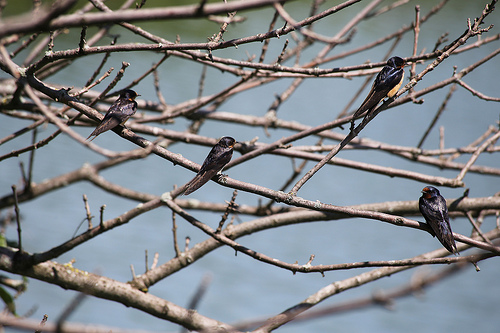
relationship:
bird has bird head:
[417, 184, 456, 251] [418, 180, 443, 197]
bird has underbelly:
[352, 57, 404, 123] [389, 70, 404, 98]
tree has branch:
[0, 3, 499, 330] [161, 192, 471, 265]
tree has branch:
[0, 3, 499, 330] [213, 36, 498, 75]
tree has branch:
[0, 3, 499, 330] [41, 3, 368, 69]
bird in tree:
[417, 184, 456, 251] [0, 3, 499, 330]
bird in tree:
[352, 57, 404, 123] [0, 3, 499, 330]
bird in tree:
[185, 136, 238, 193] [0, 3, 499, 330]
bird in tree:
[90, 89, 142, 147] [0, 3, 499, 330]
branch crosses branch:
[260, 223, 499, 333] [161, 192, 471, 265]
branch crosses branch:
[161, 192, 471, 265] [260, 223, 499, 333]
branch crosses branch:
[41, 3, 368, 69] [213, 36, 498, 75]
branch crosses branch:
[213, 36, 498, 75] [41, 3, 368, 69]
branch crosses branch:
[3, 0, 291, 40] [41, 3, 368, 69]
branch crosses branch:
[41, 3, 368, 69] [3, 0, 291, 40]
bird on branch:
[417, 184, 456, 251] [31, 63, 498, 256]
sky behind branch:
[1, 3, 499, 332] [260, 223, 499, 333]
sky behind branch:
[1, 3, 499, 332] [161, 192, 471, 265]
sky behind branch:
[1, 3, 499, 332] [6, 94, 461, 189]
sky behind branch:
[1, 3, 499, 332] [213, 36, 498, 75]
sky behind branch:
[1, 3, 499, 332] [41, 3, 368, 69]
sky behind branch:
[1, 3, 499, 332] [3, 0, 291, 40]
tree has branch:
[0, 3, 499, 330] [7, 239, 239, 332]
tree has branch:
[0, 3, 499, 330] [3, 0, 291, 40]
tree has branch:
[0, 3, 499, 330] [6, 94, 461, 189]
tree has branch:
[0, 3, 499, 330] [260, 223, 499, 333]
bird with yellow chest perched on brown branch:
[268, 0, 499, 206] [284, 110, 354, 144]